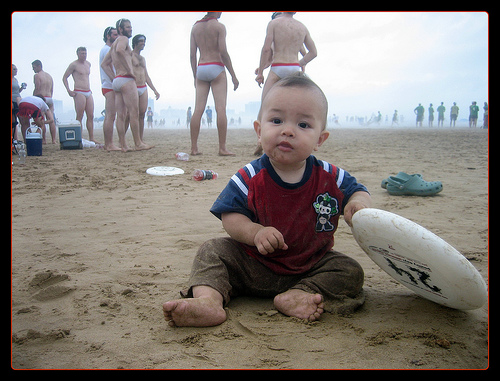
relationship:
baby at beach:
[162, 70, 372, 330] [66, 139, 474, 347]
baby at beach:
[162, 70, 372, 330] [55, 155, 452, 345]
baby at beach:
[162, 70, 372, 330] [110, 165, 439, 348]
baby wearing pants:
[162, 70, 372, 330] [178, 239, 366, 304]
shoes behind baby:
[380, 171, 440, 191] [162, 70, 372, 330]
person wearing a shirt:
[18, 96, 54, 148] [20, 96, 47, 112]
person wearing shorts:
[18, 96, 54, 148] [16, 103, 41, 118]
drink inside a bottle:
[194, 173, 217, 180] [194, 167, 219, 180]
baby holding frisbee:
[162, 64, 486, 330] [348, 205, 489, 310]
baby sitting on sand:
[162, 70, 372, 330] [11, 125, 489, 365]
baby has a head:
[162, 70, 372, 330] [253, 72, 326, 162]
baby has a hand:
[162, 70, 372, 330] [257, 225, 286, 255]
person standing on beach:
[257, 11, 316, 134] [6, 126, 486, 374]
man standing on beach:
[188, 6, 240, 156] [6, 126, 486, 374]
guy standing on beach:
[99, 16, 148, 152] [6, 126, 486, 374]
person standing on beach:
[129, 32, 156, 144] [6, 126, 486, 374]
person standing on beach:
[63, 46, 99, 141] [6, 126, 486, 374]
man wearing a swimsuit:
[185, 0, 241, 155] [192, 61, 227, 82]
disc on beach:
[146, 166, 184, 175] [6, 126, 486, 374]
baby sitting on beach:
[162, 70, 372, 330] [6, 126, 486, 374]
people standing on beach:
[18, 1, 328, 156] [17, 129, 478, 351]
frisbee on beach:
[348, 206, 489, 334] [17, 129, 478, 351]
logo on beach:
[381, 250, 434, 299] [6, 126, 486, 374]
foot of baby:
[161, 289, 229, 330] [162, 70, 372, 330]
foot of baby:
[272, 295, 328, 324] [162, 70, 372, 330]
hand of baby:
[254, 224, 285, 254] [162, 70, 372, 330]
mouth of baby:
[273, 136, 297, 154] [162, 70, 372, 330]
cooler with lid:
[58, 119, 85, 156] [57, 123, 81, 127]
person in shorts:
[18, 92, 56, 149] [15, 103, 45, 123]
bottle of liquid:
[191, 170, 220, 183] [195, 169, 217, 181]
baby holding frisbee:
[162, 70, 372, 330] [347, 200, 487, 327]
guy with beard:
[108, 16, 145, 149] [124, 29, 133, 36]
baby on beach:
[162, 70, 372, 330] [6, 126, 486, 374]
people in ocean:
[184, 103, 490, 133] [47, 96, 486, 125]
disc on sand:
[146, 166, 184, 175] [71, 125, 223, 194]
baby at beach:
[162, 70, 372, 330] [6, 126, 486, 374]